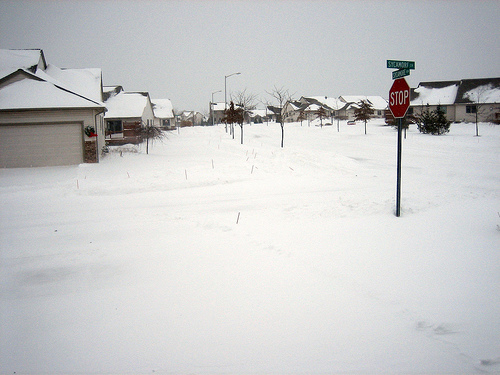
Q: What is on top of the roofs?
A: Snow.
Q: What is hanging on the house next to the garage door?
A: A Christmas Wreath with a red bow.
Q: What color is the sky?
A: Grey.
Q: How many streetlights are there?
A: Two.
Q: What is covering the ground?
A: Snow.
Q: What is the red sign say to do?
A: Stop.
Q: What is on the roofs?
A: White Snow.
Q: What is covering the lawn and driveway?
A: Snow.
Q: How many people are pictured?
A: None.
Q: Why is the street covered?
A: Snow.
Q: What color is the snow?
A: White.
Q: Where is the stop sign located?
A: On the right.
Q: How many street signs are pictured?
A: Two.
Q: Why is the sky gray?
A: Winter sky.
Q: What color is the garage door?
A: Tan.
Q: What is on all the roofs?
A: Snow.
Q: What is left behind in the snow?
A: Footprints.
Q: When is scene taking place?
A: Winter.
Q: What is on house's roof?
A: Snow.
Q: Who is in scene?
A: No one.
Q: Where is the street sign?
A: On top of stop sign.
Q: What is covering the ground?
A: Snow.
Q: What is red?
A: Stop sign.